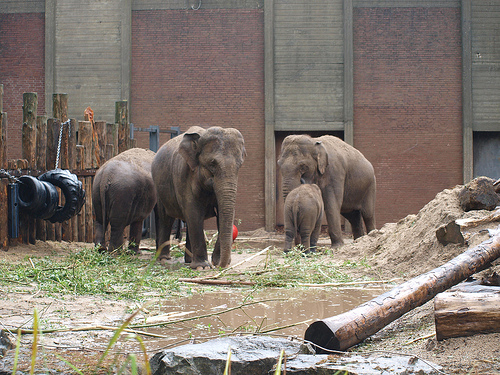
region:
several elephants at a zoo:
[14, 39, 393, 273]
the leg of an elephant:
[186, 213, 208, 268]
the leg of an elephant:
[151, 208, 177, 261]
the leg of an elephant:
[106, 223, 125, 256]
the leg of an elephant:
[126, 218, 144, 250]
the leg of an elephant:
[85, 218, 108, 253]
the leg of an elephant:
[281, 225, 296, 253]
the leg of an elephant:
[301, 225, 311, 253]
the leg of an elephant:
[321, 193, 351, 245]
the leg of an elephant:
[363, 195, 384, 237]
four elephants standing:
[94, 123, 385, 263]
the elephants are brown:
[89, 123, 383, 251]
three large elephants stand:
[96, 130, 378, 266]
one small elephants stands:
[283, 181, 316, 251]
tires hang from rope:
[20, 167, 85, 225]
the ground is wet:
[89, 289, 383, 366]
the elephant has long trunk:
[218, 173, 234, 273]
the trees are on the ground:
[302, 232, 497, 355]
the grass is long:
[4, 312, 296, 369]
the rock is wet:
[151, 350, 433, 367]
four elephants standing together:
[91, 123, 379, 263]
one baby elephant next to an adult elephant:
[279, 175, 327, 250]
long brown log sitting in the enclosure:
[305, 225, 495, 355]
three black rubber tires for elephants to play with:
[10, 163, 87, 225]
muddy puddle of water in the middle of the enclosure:
[85, 272, 385, 374]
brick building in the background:
[6, 5, 497, 237]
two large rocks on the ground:
[150, 319, 436, 373]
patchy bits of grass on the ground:
[17, 236, 399, 307]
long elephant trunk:
[209, 165, 244, 272]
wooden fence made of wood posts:
[3, 85, 163, 255]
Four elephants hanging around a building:
[67, 116, 416, 286]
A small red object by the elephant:
[227, 225, 247, 245]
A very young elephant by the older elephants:
[277, 183, 333, 248]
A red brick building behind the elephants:
[4, 0, 489, 152]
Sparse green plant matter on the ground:
[27, 254, 178, 297]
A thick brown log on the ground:
[297, 231, 495, 353]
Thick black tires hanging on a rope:
[14, 159, 91, 227]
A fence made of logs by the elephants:
[10, 83, 158, 253]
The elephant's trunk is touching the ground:
[214, 174, 244, 274]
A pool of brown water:
[197, 289, 337, 340]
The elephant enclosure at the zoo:
[3, 1, 498, 368]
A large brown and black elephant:
[151, 123, 245, 270]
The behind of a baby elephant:
[282, 187, 326, 252]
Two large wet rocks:
[149, 337, 436, 374]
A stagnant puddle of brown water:
[147, 291, 362, 341]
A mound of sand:
[347, 172, 498, 278]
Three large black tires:
[18, 165, 88, 223]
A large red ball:
[227, 222, 244, 239]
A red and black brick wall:
[353, 5, 463, 153]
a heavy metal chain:
[52, 119, 71, 166]